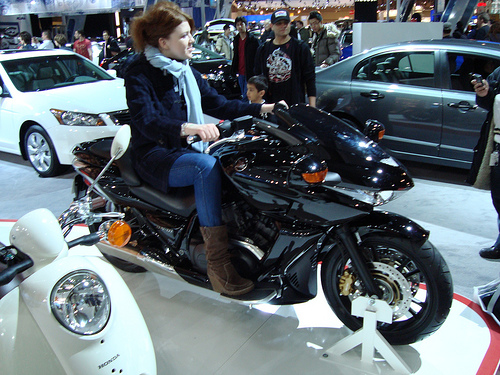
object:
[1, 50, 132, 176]
car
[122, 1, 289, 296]
woman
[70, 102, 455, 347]
bike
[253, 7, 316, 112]
man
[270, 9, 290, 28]
hat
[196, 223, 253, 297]
boot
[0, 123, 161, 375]
scooter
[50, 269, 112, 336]
headlight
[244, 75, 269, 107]
boy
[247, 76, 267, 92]
hair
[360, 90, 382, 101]
handle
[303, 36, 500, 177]
car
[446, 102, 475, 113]
handle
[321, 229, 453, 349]
wheel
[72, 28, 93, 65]
man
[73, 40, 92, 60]
shirt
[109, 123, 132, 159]
mirror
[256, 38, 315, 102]
shirt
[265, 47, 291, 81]
design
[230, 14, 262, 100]
man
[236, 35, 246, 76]
shirt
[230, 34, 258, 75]
jacket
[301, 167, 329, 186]
blinker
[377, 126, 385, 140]
blinker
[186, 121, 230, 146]
handle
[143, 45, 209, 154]
scarf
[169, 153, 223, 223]
jeans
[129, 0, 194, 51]
hair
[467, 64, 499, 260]
person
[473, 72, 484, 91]
phone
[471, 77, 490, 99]
hand